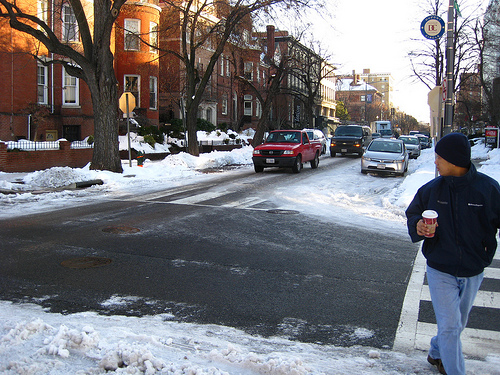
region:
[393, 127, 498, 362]
A man crossing the street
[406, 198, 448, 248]
A coffee cup in the man's right hand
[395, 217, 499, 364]
A crosswalk on the street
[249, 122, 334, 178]
A red truck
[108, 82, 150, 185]
The back of a stop sign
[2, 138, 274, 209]
Piles of snow by the street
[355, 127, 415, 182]
A small silver car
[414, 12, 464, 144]
A sign by the street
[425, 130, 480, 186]
A black ski cap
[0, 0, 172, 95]
Sunlight on the buildings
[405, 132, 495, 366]
Man looking behind him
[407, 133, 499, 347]
man crossing the snowy street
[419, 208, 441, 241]
red to go coffee cup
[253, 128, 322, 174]
small red ford truck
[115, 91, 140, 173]
back side of a stop sign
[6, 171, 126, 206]
snow covered sidewalks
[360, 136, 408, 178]
small silver car parked on the street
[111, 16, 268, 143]
red brick homes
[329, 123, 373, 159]
black van with orange lights on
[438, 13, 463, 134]
gray light pole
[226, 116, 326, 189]
a red truck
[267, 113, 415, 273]
the road is covered in snow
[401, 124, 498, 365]
the man is holding a red cup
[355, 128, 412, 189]
a silver car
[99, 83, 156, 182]
the back of a stop sign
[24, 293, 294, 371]
the snow is white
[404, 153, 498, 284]
the man is wearing a black jacket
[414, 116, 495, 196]
the man's hat is black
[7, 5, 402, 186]
the buildings are brown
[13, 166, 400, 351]
the road is gray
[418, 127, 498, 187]
man wearing navy blue stocking cap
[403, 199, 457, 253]
man carrying coffee in right hand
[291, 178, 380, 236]
snow and ice on roadway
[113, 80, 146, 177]
back of stop sign reflecting the sun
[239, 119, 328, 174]
red pick up truck approaching stop sign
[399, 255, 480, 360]
white markings on pavement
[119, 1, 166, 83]
windows in red brick home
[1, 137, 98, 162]
brick and wrought iron fencing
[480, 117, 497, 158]
red blue and white real estate sign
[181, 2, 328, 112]
bare trees in winter season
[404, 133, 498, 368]
man walking on crosswalk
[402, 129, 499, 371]
man holding coffee cup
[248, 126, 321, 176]
red truck driving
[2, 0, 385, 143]
block of buildings along street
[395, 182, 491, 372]
crosswalk for pedestrians to walk across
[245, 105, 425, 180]
several cars driving down the street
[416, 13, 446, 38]
round sign on pole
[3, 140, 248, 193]
snow piled along the street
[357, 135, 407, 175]
silver sedan on street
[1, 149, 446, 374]
road intersection